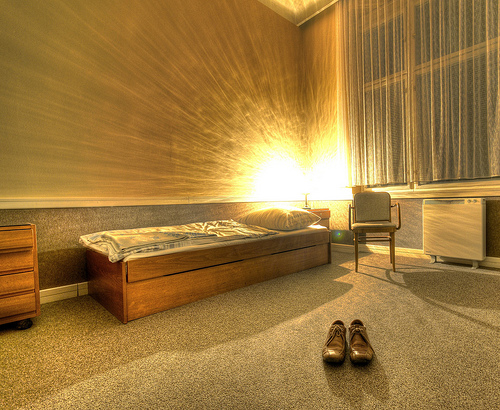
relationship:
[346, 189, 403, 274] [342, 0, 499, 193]
chair near window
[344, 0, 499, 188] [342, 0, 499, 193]
drapes on window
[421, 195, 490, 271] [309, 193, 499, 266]
unit on wall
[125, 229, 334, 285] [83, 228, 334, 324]
drawer in frame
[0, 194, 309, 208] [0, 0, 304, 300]
rail on wall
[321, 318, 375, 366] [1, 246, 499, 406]
shoes on floor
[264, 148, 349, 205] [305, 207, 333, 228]
light on nightstand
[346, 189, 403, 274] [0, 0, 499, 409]
chair in room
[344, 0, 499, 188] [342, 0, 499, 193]
curtains on window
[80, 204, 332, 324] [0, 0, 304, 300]
bed against wall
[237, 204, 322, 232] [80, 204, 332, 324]
pillow on bed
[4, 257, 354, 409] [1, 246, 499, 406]
shadow on carpet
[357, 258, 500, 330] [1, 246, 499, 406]
shadow on carpet